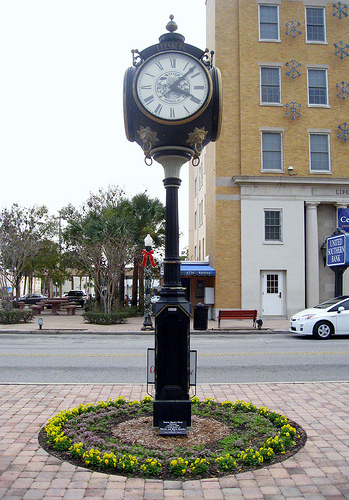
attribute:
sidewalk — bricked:
[1, 380, 347, 498]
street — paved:
[1, 330, 348, 382]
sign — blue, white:
[324, 233, 348, 267]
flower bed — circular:
[41, 394, 301, 481]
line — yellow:
[2, 347, 349, 360]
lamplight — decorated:
[139, 230, 157, 333]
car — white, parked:
[287, 292, 348, 340]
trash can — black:
[191, 297, 210, 333]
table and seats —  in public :
[28, 295, 83, 319]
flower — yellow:
[168, 458, 179, 468]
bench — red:
[214, 307, 259, 332]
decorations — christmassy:
[141, 249, 153, 321]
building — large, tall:
[184, 1, 348, 323]